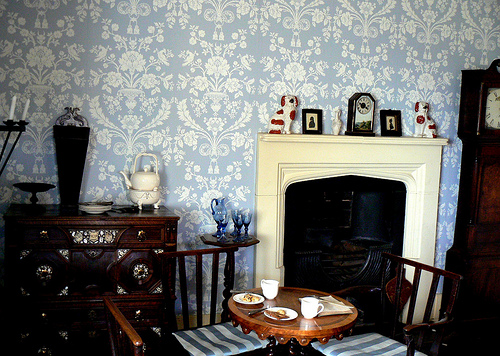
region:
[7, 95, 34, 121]
Two long white candles.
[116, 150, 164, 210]
A white teapot on a shelf.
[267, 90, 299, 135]
Statue of a white and red dog on the fireplace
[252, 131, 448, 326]
a white fireplace in a kitchen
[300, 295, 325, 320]
A white tea cup on a table with food.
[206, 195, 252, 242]
A blue drink set on a small table.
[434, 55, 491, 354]
A grandfather clock in the corner of the room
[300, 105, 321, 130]
A photo silhouette of a person on the fireplace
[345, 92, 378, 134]
A small clock on the fireplace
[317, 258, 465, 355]
A chair with blue and white stripes.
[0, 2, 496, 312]
blue wallpaper with white design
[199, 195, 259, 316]
glassware on small table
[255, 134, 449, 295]
fireplace with white mantel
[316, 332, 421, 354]
striped seat of chair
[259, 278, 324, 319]
two white cups with handles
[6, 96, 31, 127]
two white candles in holders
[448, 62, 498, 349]
grandfather clock with white face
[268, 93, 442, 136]
two dog figurines on mantel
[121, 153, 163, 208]
white teapot with handle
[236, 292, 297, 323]
two plates with food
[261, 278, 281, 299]
Crisp white coffee cup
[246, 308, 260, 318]
Silver metallic cutlery piece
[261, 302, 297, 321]
Snack on white saucer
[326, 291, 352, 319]
Pieces of paper serviette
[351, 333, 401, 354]
Stripped white and blue seat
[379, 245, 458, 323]
Shiny narrow wooden bars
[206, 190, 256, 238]
Antique pieces of glass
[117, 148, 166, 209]
Crisp white antique kettle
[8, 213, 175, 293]
A shiny valuable cabinet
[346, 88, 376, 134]
Small black antique clock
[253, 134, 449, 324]
white mantle around fireplace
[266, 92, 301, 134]
dog ornament on fireplace mantle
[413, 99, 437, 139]
dog ornament on fireplace mantle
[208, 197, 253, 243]
blue glassware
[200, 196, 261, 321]
blue glassware sitting on a table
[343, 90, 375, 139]
smal clock sitting on mantle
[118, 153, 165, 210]
white teapot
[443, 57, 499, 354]
standing wooden clock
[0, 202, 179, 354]
wooden chest of drawers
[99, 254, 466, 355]
chairs and table set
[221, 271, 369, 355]
An English tea table with tea and scones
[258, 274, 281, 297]
A white tea cup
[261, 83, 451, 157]
A fireplace mantle decorated with accessories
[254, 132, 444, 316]
A cream colored fireplace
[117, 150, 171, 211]
A classic English teapot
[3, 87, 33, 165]
Part of an iron candlebra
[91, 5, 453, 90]
An area of light blue and white decorative wallpaper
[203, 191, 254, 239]
An iceblue glass waterpitcher and glasses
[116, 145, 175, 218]
A white English teakettle